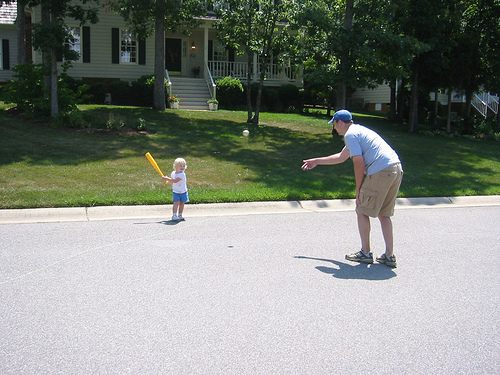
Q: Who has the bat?
A: The child.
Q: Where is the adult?
A: In the street.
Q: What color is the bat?
A: Yellow.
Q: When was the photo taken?
A: Daytime.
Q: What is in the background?
A: A house.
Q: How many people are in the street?
A: Two.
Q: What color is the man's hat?
A: Blue.